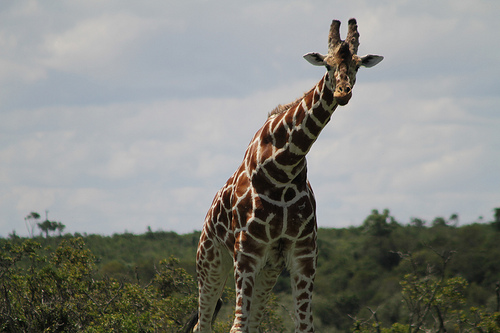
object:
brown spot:
[260, 135, 287, 159]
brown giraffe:
[179, 18, 382, 333]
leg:
[288, 232, 320, 333]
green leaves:
[38, 261, 114, 313]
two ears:
[303, 51, 385, 68]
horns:
[328, 18, 360, 61]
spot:
[280, 192, 316, 241]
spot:
[233, 253, 258, 277]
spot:
[269, 212, 291, 226]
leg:
[228, 233, 272, 332]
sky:
[0, 0, 499, 240]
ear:
[361, 53, 385, 68]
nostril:
[345, 86, 351, 93]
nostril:
[338, 85, 342, 91]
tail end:
[178, 313, 198, 333]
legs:
[248, 251, 286, 333]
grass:
[324, 229, 489, 295]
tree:
[342, 245, 498, 332]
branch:
[368, 307, 378, 330]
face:
[323, 53, 362, 105]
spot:
[279, 184, 301, 204]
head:
[302, 18, 384, 107]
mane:
[267, 85, 316, 117]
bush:
[0, 210, 197, 333]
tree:
[16, 211, 72, 239]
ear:
[301, 51, 326, 67]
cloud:
[49, 17, 150, 71]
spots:
[295, 272, 317, 289]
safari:
[0, 0, 500, 333]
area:
[0, 0, 500, 331]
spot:
[286, 101, 311, 135]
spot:
[236, 179, 255, 200]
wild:
[0, 208, 500, 333]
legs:
[195, 231, 233, 333]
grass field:
[1, 222, 498, 333]